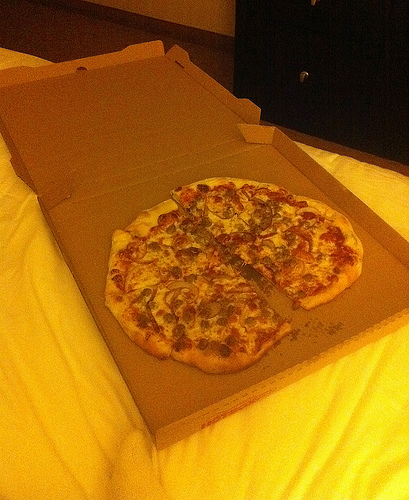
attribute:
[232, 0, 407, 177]
furniture — black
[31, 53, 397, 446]
box — tasty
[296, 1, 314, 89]
knobs — silver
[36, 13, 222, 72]
flooring — dark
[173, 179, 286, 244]
pizza — slice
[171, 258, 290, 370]
pizza — slice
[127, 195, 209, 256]
pizza — slice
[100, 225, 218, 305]
pizza — slice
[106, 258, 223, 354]
pizza — slice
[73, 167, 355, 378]
pizza — flavorful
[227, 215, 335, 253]
pizza — slice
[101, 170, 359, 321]
pizza — good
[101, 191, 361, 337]
pizza — chunky cheese, cheese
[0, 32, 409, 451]
box — brown, cardboard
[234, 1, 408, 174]
dresser — black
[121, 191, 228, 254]
pizza — slice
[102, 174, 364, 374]
pizza — hot, round, seasoned, delicious, great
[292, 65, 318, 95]
knob — round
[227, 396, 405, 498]
cloth — yellow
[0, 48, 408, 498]
sheet — yellow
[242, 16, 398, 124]
dresser — black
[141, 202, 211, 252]
pizza — slice